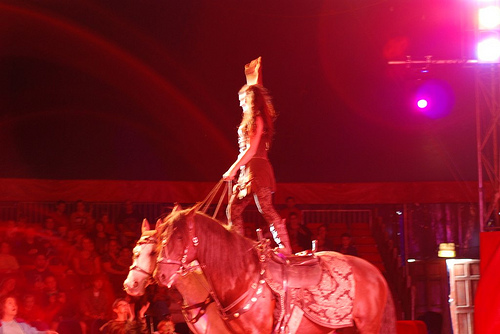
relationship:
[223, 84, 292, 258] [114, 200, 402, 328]
person standing on horses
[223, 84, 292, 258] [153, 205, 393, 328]
person standing on horse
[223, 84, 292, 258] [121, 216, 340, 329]
person standing on horse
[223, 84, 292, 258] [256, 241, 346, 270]
person standing on back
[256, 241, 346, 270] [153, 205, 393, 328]
back of horse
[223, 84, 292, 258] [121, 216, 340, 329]
person of horse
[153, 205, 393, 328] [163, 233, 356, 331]
horse wearing tack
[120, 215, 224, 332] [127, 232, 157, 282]
horse with bridle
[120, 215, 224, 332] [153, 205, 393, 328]
horse standing behind horse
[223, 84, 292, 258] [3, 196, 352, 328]
person performing in front of audience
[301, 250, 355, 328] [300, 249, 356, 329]
blanket with pattern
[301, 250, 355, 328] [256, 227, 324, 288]
blanket under saddle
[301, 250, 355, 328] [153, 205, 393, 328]
blanket on horse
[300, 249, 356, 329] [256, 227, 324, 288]
pattern under saddle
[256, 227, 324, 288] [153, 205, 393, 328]
saddle on horse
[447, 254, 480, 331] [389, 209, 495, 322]
door in background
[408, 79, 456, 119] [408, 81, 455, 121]
spotlight with halo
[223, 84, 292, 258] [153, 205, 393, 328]
person on horse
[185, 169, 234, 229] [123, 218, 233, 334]
reins to horse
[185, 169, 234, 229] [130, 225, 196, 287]
reins to bridals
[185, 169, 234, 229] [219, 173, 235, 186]
reins held in hands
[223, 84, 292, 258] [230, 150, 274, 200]
person wearing skirt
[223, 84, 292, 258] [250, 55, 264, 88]
person with hand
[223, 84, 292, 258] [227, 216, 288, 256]
person wearing boots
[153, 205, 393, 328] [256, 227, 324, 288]
horse with saddle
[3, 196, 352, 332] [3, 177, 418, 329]
people sitting in stands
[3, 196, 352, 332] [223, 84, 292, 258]
people watching person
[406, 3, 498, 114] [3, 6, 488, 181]
lights on ceiling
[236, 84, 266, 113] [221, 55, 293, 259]
head of a person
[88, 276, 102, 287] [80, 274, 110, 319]
head of a person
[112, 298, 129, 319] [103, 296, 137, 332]
head of a person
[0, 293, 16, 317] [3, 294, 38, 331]
head of a person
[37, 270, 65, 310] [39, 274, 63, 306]
head of a person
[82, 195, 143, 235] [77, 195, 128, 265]
head of a person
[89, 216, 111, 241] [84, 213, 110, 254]
head of a person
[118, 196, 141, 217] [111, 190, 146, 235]
head of a person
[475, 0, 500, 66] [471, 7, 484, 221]
lights on metal frame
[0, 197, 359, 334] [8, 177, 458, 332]
audience sitting from stands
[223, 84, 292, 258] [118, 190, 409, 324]
person standing on horses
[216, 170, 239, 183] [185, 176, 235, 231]
hands on reigns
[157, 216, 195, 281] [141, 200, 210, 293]
bridle on head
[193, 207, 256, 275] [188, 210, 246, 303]
mane on neck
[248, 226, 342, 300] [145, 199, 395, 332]
saddle on back of horse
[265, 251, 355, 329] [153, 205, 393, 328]
blanket on horse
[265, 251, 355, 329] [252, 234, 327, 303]
blanket under saddle